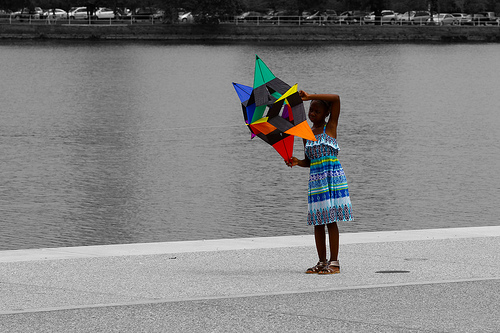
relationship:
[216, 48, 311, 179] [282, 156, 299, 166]
kite in hand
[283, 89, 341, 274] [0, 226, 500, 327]
girl on sidewalk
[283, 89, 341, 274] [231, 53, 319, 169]
girl holding kite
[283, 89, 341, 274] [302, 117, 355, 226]
girl in dress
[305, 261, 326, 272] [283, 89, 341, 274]
sandal on girl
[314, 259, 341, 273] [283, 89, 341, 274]
sandal on girl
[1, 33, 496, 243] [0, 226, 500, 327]
water by sidewalk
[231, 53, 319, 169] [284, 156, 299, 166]
kite in hand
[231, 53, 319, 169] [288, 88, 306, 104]
kite in hand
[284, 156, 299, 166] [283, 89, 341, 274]
hand of girl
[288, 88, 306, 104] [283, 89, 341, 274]
hand of girl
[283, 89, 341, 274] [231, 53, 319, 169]
girl with kite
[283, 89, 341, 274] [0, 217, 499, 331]
girl on sidewalk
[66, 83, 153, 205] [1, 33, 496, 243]
ripples on water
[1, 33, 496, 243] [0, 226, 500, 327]
water on sidewalk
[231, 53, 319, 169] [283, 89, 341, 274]
kite with girl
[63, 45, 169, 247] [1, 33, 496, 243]
ripples in water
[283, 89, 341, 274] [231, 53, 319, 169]
girl preparing to fly a kite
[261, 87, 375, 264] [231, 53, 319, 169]
girl holding kite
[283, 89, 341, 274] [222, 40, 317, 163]
girl holding kite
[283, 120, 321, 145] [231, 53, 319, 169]
triangle on kite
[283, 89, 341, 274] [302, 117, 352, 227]
girl wearing dress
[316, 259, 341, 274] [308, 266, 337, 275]
sandal on feet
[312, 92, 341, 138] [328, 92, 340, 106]
arm bent at elbow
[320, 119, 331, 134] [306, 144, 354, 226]
strap of dress